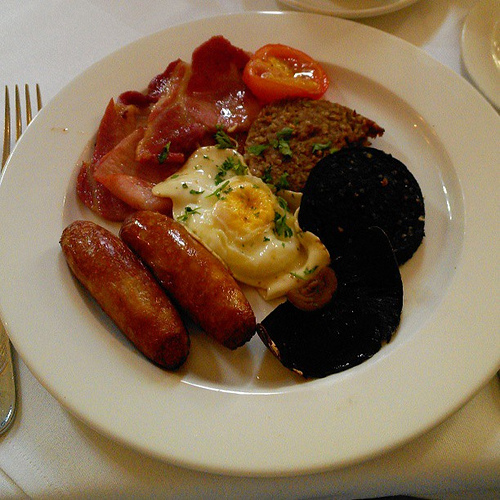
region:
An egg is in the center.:
[163, 145, 333, 291]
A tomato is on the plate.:
[241, 36, 333, 104]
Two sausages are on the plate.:
[57, 197, 261, 373]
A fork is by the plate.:
[1, 81, 44, 168]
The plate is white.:
[12, 14, 477, 473]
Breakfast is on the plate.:
[73, 46, 423, 351]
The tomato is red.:
[245, 39, 327, 103]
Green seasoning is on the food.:
[196, 117, 339, 260]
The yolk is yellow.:
[218, 179, 271, 223]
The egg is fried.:
[152, 142, 327, 300]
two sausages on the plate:
[57, 194, 249, 389]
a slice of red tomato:
[234, 28, 341, 115]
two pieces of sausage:
[61, 214, 255, 365]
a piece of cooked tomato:
[244, 43, 329, 100]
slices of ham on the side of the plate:
[81, 35, 256, 220]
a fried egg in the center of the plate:
[152, 143, 329, 296]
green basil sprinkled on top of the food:
[162, 125, 327, 240]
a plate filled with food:
[2, 12, 496, 474]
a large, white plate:
[1, 9, 496, 471]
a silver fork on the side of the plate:
[0, 83, 40, 437]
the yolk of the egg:
[219, 185, 271, 229]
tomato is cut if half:
[243, 43, 328, 99]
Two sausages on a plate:
[56, 218, 258, 377]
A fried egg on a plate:
[155, 140, 330, 292]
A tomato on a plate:
[243, 44, 330, 98]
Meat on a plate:
[79, 31, 258, 219]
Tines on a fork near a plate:
[2, 83, 37, 158]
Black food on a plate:
[257, 143, 423, 369]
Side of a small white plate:
[457, 9, 497, 102]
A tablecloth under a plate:
[11, 430, 117, 498]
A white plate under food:
[0, 11, 498, 479]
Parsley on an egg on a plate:
[267, 200, 294, 239]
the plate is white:
[1, 10, 498, 476]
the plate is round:
[0, 11, 499, 474]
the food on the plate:
[0, 11, 499, 476]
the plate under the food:
[0, 10, 497, 476]